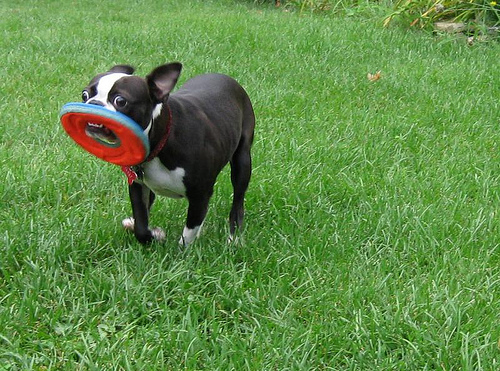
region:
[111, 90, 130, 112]
the eye of a dog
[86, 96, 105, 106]
the nose of a dog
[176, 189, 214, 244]
the leg of a dog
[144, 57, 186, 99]
the ear of a dog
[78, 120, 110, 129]
the teeth of a dog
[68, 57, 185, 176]
the head of a dog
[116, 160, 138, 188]
a red dog tag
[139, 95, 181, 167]
a red dog collar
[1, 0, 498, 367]
a green grassy lawn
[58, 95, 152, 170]
a dog toy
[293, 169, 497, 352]
green grass growing on ground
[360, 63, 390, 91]
a brown leaf in grass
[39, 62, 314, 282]
a small black dog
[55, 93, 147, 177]
a red and blue dog toy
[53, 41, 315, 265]
a dog with a toy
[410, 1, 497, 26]
plants with green leaves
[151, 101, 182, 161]
a red dog collar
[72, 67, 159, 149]
face of a black and white dog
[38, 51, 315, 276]
a black and white dog running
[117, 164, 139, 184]
dog tag on collar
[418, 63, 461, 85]
part of a grass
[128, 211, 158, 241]
part of a leg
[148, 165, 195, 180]
chest of a dog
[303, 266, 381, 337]
part of some grass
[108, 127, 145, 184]
part of a dish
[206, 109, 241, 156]
part of a stomach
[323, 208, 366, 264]
part of a grass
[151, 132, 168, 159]
part of a belt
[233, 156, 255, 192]
part of a knee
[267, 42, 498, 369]
The grass is green.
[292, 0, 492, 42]
The plants are green.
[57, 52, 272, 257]
Dog playing in the grass.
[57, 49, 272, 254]
Only one dog visible.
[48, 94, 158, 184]
Frisbee in dogs mouth.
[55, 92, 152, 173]
Frisbee is red and blue.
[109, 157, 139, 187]
Dog's tag is red.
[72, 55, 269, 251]
The dog is black and white.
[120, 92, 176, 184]
The dog's collar is red.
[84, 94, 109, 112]
The dog's nose is black.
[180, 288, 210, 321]
small green sliver of grass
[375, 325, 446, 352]
tiny white grass on ground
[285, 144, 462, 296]
large green patch of grass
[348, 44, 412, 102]
small yellow leaf on grass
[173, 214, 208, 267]
white feet on black dog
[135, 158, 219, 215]
white underbelly of dog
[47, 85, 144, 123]
large bug eyes on dog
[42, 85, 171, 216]
round blue and red object on dog's face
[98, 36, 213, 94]
large ears on black dog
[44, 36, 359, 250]
large black and white dog in grass